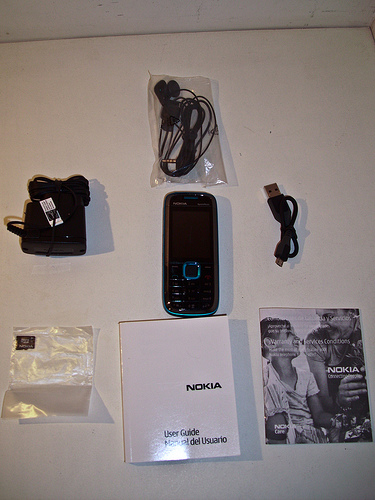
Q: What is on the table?
A: A user guide.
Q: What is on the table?
A: A warranty book.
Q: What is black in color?
A: The phone.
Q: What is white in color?
A: The surface.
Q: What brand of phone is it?
A: Nokia.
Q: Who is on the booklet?
A: Two people.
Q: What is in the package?
A: Headphones.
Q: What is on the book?
A: A picture of people.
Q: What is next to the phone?
A: A cord.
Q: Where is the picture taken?
A: On the table.